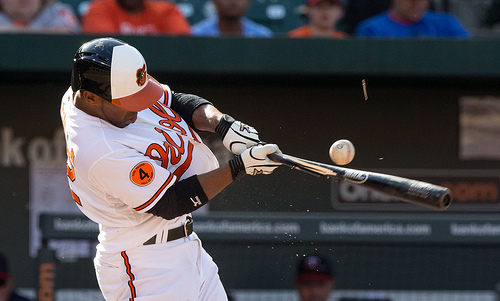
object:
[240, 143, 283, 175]
gloves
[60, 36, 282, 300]
player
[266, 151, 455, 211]
bat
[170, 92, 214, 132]
sleeves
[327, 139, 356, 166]
ball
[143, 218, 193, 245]
belt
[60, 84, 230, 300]
uniform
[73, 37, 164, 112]
helmet